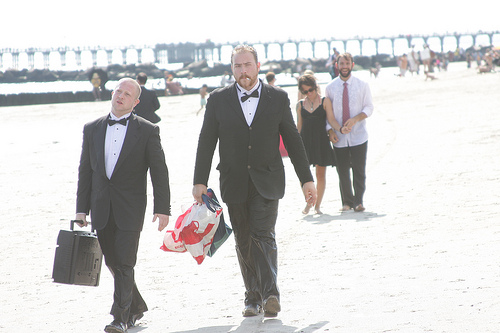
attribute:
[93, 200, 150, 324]
pants — black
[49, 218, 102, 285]
case — black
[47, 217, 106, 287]
stereo — black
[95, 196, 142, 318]
pants — black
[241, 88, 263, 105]
bow tie — crooked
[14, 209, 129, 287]
radio — black, large, plastic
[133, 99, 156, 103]
ear —  man's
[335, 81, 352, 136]
tie — red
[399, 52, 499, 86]
people —  Crowd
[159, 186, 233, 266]
bags — few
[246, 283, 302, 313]
shoe — dress shoe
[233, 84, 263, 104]
tie — black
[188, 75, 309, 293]
coat — black